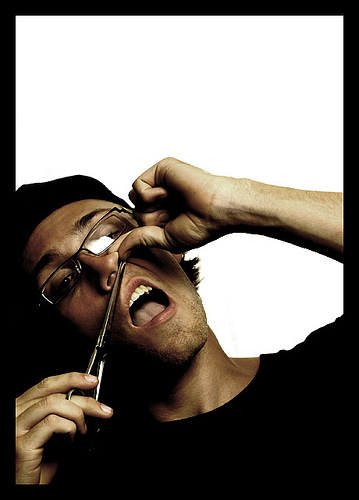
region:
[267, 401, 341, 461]
man wearing black shirt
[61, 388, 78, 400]
scissor ring around finger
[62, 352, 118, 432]
man with scissors in hand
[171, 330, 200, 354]
black hair on chin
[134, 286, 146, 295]
teeth in mans mouth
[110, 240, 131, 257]
mans fingers on nose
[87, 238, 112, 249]
light reflecting in glasses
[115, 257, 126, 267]
scissors in mans nose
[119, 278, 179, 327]
mans mouth is open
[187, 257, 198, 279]
man has black hair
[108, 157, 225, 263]
his hand is holding his nose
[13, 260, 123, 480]
his hand is holding scissors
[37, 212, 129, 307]
black framed eye glasses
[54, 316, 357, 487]
a plain black tee shirt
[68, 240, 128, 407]
scissors are cutting nose hairs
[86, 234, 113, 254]
reflection on the lens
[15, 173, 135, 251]
a black hat on his head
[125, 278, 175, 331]
his mouth is open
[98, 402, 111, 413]
no nail polish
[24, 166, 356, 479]
man with scissors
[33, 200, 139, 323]
the man wearing glasses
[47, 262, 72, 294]
lens of the glasses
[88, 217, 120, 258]
lens of the glasses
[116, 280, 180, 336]
the mouth is open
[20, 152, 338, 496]
man cutting nose hairs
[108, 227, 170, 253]
fingers holding the nostril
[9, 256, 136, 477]
the hand holding the scissors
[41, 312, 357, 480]
the man wearing black t shirt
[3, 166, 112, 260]
the man wearing black hat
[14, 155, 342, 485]
a man trimming his nose hairs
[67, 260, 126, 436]
a pair of hair trimming scissors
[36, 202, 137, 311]
glasses on a man's face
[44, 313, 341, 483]
a black shirt on a man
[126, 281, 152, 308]
upper teeth in a man's mouth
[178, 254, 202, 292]
a man's hair behind his ear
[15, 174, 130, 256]
a black beret on a man's head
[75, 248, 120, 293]
the nose of a man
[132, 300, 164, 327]
the tongue of a man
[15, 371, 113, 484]
a man's hand holding scissors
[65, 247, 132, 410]
a pair of scissors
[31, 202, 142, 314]
glasses on face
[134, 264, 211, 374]
hair on face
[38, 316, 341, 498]
a black shirt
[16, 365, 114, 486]
the right hand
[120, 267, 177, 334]
mouth wide open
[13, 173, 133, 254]
a black hat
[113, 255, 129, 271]
a man clearing nose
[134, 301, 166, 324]
a pink tongue